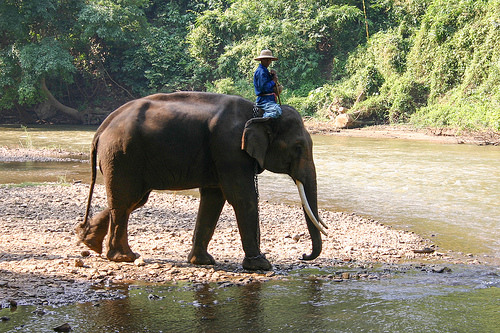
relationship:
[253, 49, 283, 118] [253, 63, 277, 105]
man wearing blue shirt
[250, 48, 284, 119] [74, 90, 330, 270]
man riding elephant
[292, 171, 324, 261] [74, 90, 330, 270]
trunk of elephant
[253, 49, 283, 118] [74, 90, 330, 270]
man on elephant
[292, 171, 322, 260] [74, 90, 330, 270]
trunk on elephant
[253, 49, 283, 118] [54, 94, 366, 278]
man on elephant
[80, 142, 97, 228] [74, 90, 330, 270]
tail on elephant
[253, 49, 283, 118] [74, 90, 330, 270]
man riding a elephant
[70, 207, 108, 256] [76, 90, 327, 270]
foot on a elephant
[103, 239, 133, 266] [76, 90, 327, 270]
foot on a elephant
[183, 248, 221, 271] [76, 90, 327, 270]
foot on a elephant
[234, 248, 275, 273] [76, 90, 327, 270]
foot on a elephant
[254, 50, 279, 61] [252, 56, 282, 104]
hat on a man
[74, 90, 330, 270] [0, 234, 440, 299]
elephant on a rock bank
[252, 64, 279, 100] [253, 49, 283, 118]
blue shirt on a man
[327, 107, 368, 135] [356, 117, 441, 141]
tree trunk on ground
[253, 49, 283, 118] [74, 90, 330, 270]
man on a elephant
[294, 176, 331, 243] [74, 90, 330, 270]
white tusks on a elephant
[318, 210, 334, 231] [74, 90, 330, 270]
white tusks on a elephant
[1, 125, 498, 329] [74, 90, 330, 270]
water around elephant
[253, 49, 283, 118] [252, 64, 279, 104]
man wearing a blue shirt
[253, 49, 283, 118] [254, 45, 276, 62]
man wearing a hat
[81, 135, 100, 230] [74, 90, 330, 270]
tail on a elephant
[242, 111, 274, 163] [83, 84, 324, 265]
ear on a elephant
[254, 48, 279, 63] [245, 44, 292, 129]
hat on a person